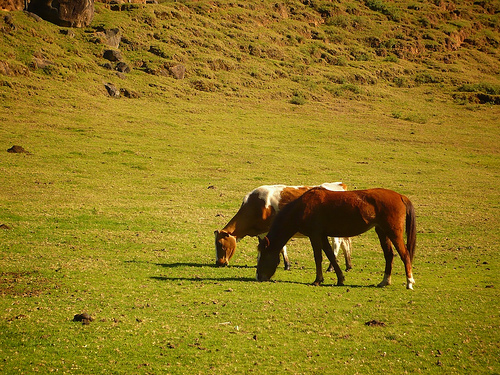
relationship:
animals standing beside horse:
[213, 182, 353, 273] [257, 189, 414, 290]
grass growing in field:
[4, 100, 499, 177] [2, 58, 497, 371]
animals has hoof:
[255, 185, 418, 289] [384, 259, 479, 334]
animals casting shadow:
[213, 182, 353, 273] [147, 257, 261, 281]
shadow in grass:
[147, 257, 261, 281] [2, 26, 499, 373]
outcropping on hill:
[0, 1, 499, 93] [0, 0, 498, 103]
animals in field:
[213, 182, 353, 273] [3, 90, 495, 373]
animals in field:
[255, 185, 418, 289] [3, 90, 495, 373]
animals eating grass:
[213, 182, 353, 273] [2, 73, 499, 370]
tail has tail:
[398, 195, 425, 272] [398, 195, 418, 264]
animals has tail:
[255, 185, 418, 289] [398, 195, 425, 272]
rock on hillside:
[97, 21, 124, 47] [2, 1, 498, 107]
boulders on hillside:
[99, 49, 137, 99] [2, 1, 498, 107]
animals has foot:
[255, 185, 418, 289] [405, 279, 418, 292]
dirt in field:
[74, 312, 93, 325] [3, 90, 495, 373]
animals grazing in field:
[255, 185, 418, 289] [3, 90, 495, 373]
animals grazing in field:
[213, 182, 353, 273] [21, 88, 497, 353]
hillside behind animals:
[3, 7, 494, 120] [206, 176, 424, 289]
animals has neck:
[213, 182, 353, 273] [216, 206, 246, 246]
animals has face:
[213, 182, 353, 273] [210, 223, 235, 284]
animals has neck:
[255, 185, 418, 289] [268, 197, 301, 247]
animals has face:
[255, 185, 418, 289] [248, 214, 300, 279]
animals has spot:
[213, 182, 353, 273] [279, 187, 311, 206]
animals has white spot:
[213, 182, 353, 273] [243, 185, 286, 210]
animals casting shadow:
[213, 182, 353, 273] [157, 256, 201, 271]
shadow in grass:
[157, 256, 201, 271] [2, 26, 499, 373]